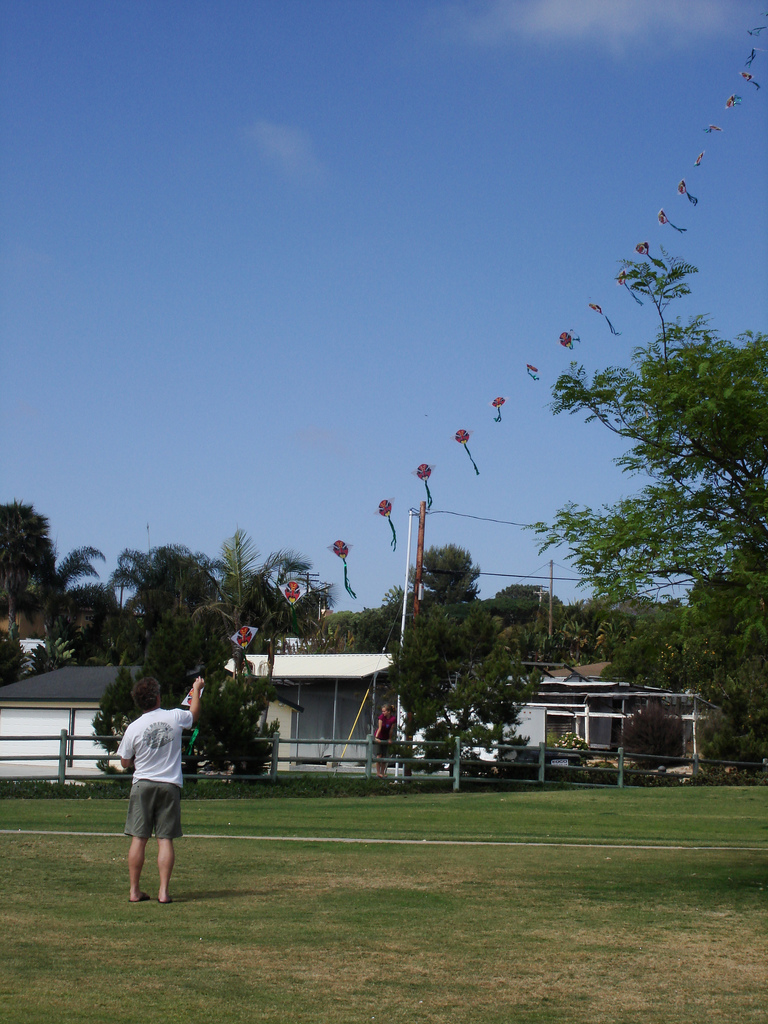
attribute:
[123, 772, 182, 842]
pants — gray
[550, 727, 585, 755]
plant — white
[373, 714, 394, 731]
shirt — red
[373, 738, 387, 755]
shorts — green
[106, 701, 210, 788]
shirt — gray